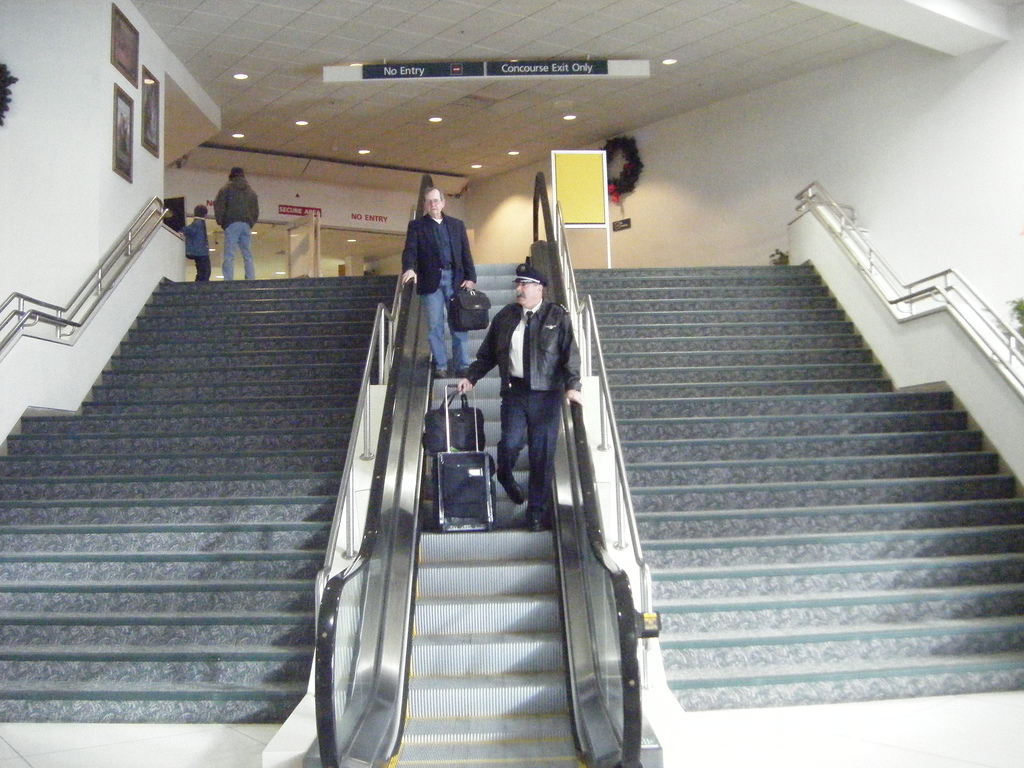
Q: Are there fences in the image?
A: No, there are no fences.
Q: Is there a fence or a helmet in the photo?
A: No, there are no fences or helmets.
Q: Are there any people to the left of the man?
A: Yes, there is a person to the left of the man.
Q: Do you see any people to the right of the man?
A: No, the person is to the left of the man.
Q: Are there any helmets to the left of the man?
A: No, there is a person to the left of the man.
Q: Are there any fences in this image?
A: No, there are no fences.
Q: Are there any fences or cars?
A: No, there are no fences or cars.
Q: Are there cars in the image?
A: No, there are no cars.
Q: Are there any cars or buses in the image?
A: No, there are no cars or buses.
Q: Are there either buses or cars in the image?
A: No, there are no cars or buses.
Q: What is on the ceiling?
A: The sign is on the ceiling.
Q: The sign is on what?
A: The sign is on the ceiling.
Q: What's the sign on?
A: The sign is on the ceiling.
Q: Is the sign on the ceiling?
A: Yes, the sign is on the ceiling.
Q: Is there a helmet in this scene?
A: No, there are no helmets.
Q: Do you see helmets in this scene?
A: No, there are no helmets.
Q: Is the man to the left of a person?
A: No, the man is to the right of a person.